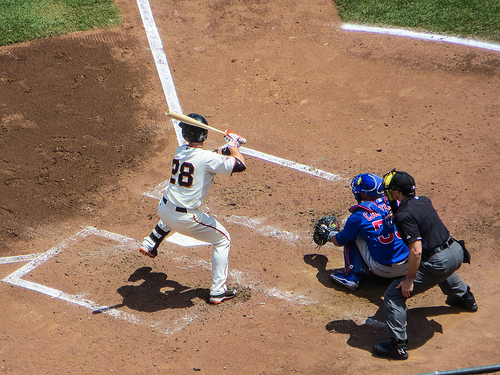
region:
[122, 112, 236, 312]
this is a baseball player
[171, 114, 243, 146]
he is holding a bat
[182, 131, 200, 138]
he is wearing a helmet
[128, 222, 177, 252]
the left leg is lifted on air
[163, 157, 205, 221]
the jersey is white in color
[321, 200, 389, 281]
the player is squatting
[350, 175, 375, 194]
the helmet is blue in color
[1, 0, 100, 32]
the grass are green in color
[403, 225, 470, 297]
the umpire is squatting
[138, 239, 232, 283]
the legs are apart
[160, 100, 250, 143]
this is a baseball bat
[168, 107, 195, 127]
the bat is made of wooden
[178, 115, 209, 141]
this is a helmet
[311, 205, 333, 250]
this is a baseball glove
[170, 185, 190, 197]
this is a white baseball t-shirt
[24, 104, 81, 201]
this is the ground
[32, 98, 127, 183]
the ground is sandy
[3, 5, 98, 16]
this is the grass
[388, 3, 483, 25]
the grass is green in color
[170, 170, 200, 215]
white baseball jersey on batter.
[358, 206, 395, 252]
blue baseball jersey on catcher.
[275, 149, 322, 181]
white chalk for batter's box.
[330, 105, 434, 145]
brown dirt on the ground.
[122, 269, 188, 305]
shadow in batter's box.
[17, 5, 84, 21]
green grass on playing field.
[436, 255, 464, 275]
gray pants on umpire.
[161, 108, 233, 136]
baseball bat in player's hands.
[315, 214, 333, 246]
baseball glove in catcher's hand.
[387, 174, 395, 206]
protective mask on umpire.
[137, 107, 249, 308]
the batter with number 28 on his uniform is ready to strike the ball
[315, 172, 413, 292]
the catcher is ready to catch the ball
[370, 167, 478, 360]
the umpire is ready to call the ball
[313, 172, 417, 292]
the catcher is wearing blue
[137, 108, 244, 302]
the batter is wearing white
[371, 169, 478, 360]
the umpire is wearing black and gray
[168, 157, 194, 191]
the number 28 is in black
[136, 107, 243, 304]
the batter has one foot off of the ground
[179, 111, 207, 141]
the batter is wearing a black helmet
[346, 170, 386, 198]
the catcher is wearing a blue hat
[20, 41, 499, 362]
players at a baseball game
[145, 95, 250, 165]
batter holding bat with both hands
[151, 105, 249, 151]
bat being held behind batter's helmet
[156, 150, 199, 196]
player's number on his back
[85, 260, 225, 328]
batter's shadow on the ground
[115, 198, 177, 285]
batter's left foot is off the ground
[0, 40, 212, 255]
ground in front of home plate appears wet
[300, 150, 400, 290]
catcher crouching low near the ground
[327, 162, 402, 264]
catcher wearing blue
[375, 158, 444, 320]
umpire resting his left hand on his leg